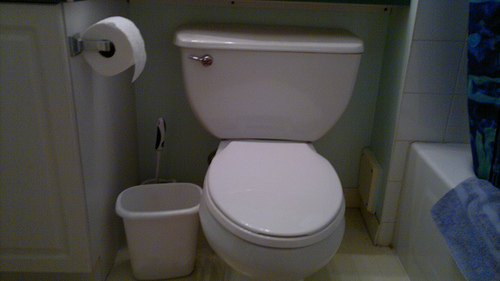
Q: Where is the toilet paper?
A: Wall.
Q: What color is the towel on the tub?
A: Blue.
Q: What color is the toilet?
A: White.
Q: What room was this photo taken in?
A: Bathroom.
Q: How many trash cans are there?
A: One.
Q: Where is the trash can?
A: Floor.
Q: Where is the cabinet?
A: Left.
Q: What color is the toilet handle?
A: Silver.